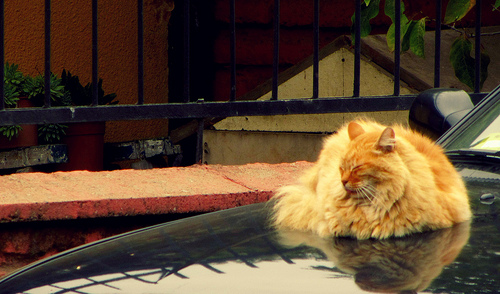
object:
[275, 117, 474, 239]
cat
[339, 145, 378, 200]
face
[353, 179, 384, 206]
whiskers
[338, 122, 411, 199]
head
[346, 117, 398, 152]
ears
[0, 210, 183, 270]
wall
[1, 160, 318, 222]
top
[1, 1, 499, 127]
railing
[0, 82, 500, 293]
car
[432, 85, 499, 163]
windshield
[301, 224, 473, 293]
reflection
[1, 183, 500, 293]
hood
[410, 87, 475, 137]
mirror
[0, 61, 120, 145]
leaves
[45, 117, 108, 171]
pot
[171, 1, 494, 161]
shed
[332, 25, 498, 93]
roof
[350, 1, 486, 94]
leaves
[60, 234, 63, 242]
line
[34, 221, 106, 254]
brick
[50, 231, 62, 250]
crack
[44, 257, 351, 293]
reflection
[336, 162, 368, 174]
eyes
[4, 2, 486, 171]
building